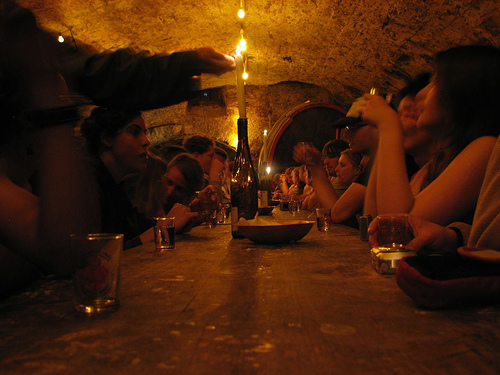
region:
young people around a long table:
[1, 0, 491, 374]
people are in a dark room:
[12, 8, 492, 368]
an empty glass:
[56, 215, 128, 327]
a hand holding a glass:
[353, 197, 455, 288]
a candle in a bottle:
[219, 40, 266, 227]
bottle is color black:
[224, 113, 267, 228]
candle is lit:
[230, 36, 251, 117]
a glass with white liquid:
[149, 198, 183, 259]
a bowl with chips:
[228, 208, 319, 253]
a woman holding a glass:
[343, 32, 499, 244]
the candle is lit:
[180, 36, 269, 132]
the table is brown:
[188, 256, 350, 363]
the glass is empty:
[51, 228, 154, 314]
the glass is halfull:
[147, 210, 180, 254]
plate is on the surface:
[225, 210, 320, 240]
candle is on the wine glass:
[224, 50, 264, 230]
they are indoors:
[22, 20, 466, 343]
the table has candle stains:
[252, 310, 363, 364]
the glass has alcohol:
[150, 215, 174, 250]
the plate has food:
[241, 206, 329, 251]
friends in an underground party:
[9, 3, 485, 373]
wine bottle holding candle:
[232, 32, 255, 239]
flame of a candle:
[227, 33, 250, 59]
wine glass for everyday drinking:
[65, 226, 118, 316]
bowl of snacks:
[232, 213, 317, 243]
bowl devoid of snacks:
[395, 245, 498, 317]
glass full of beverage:
[151, 210, 179, 255]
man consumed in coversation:
[165, 155, 210, 235]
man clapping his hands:
[291, 120, 374, 220]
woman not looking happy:
[82, 105, 160, 245]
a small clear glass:
[67, 232, 123, 315]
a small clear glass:
[153, 216, 175, 247]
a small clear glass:
[374, 213, 412, 270]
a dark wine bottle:
[230, 115, 259, 217]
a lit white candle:
[232, 43, 247, 117]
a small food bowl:
[233, 215, 315, 246]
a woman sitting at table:
[348, 48, 495, 234]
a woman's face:
[333, 148, 355, 185]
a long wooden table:
[2, 203, 499, 374]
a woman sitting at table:
[80, 101, 223, 240]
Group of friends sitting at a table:
[44, 31, 486, 282]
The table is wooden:
[160, 258, 303, 370]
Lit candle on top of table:
[222, 43, 302, 249]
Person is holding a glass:
[356, 170, 438, 295]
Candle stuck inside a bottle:
[221, 26, 272, 213]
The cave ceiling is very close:
[65, 18, 374, 113]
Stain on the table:
[195, 300, 257, 369]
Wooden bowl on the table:
[205, 202, 337, 266]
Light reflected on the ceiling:
[259, 13, 340, 68]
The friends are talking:
[287, 103, 424, 247]